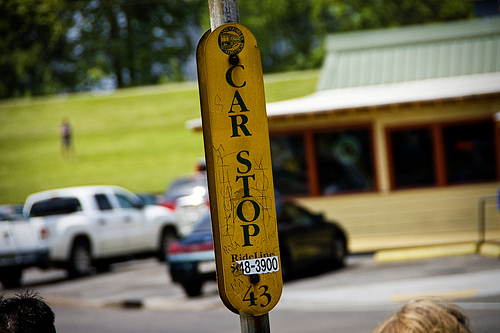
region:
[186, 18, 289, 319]
a sign on the pole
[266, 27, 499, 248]
a restaurant with customers in it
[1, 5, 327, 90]
the green trees at the end of the field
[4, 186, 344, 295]
cars in the parking lot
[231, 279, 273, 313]
the number on the sign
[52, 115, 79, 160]
the person standing in the field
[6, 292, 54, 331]
the dark hair the person by the pole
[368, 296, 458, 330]
the blonde hair of the other person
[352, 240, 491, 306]
empty parking spaces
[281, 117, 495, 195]
the windows of the restaurant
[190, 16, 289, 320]
a long sign in a pole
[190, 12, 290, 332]
sign is brown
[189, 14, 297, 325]
sign says "car stop"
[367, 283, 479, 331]
hair is blonde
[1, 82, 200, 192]
a field cover with green grass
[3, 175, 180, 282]
a white truck parked near a building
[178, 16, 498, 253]
building has green roof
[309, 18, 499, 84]
green roof of building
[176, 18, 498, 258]
building is green and yellow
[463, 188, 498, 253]
part of a rail can be seen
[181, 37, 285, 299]
The sign is yellow.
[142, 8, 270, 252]
The sign is yellow.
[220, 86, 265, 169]
this is a post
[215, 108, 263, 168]
the post is wooden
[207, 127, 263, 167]
the post is brown in color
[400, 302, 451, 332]
the hair is pale brown in color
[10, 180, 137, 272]
this is a truck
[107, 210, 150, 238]
the truck is white in color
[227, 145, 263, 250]
it is written stop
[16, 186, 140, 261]
the truck is parked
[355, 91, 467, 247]
this is a restaurant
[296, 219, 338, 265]
the car is black in color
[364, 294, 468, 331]
top of a blond head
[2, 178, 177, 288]
white truck parked in a parking lot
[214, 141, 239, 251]
graffiti that just looks like scribbles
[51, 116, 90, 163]
person standing on the green grass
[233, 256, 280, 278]
ripped white sticker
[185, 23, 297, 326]
gold and black sign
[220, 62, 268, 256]
vertical black writing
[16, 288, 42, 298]
tiny black hairs sticking up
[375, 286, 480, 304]
yellow line on the ground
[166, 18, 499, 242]
building